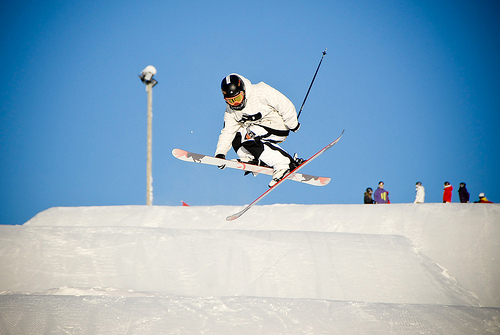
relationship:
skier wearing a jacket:
[213, 70, 308, 186] [208, 73, 298, 137]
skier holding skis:
[213, 70, 308, 189] [168, 146, 333, 190]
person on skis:
[212, 71, 313, 181] [169, 131, 340, 218]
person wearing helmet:
[212, 71, 303, 188] [221, 73, 245, 96]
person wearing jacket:
[212, 71, 303, 188] [208, 82, 300, 155]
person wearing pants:
[212, 71, 303, 188] [234, 119, 297, 173]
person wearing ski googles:
[212, 71, 303, 188] [225, 91, 244, 105]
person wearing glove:
[212, 71, 303, 188] [210, 149, 228, 162]